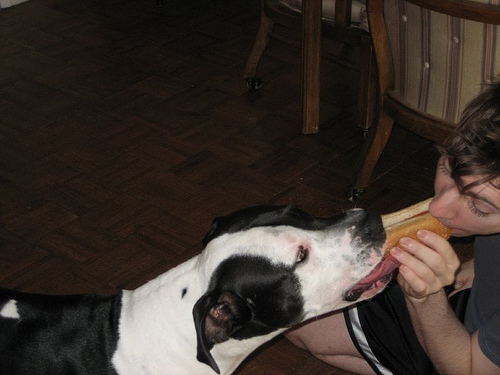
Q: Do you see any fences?
A: No, there are no fences.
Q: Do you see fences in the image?
A: No, there are no fences.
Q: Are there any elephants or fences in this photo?
A: No, there are no fences or elephants.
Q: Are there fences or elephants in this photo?
A: No, there are no fences or elephants.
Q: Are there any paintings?
A: No, there are no paintings.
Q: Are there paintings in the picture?
A: No, there are no paintings.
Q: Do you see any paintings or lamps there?
A: No, there are no paintings or lamps.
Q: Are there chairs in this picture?
A: Yes, there is a chair.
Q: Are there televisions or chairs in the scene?
A: Yes, there is a chair.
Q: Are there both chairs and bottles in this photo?
A: No, there is a chair but no bottles.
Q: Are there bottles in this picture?
A: No, there are no bottles.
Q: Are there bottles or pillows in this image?
A: No, there are no bottles or pillows.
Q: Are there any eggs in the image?
A: No, there are no eggs.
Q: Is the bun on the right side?
A: Yes, the bun is on the right of the image.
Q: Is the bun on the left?
A: No, the bun is on the right of the image.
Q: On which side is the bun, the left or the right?
A: The bun is on the right of the image.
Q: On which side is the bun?
A: The bun is on the right of the image.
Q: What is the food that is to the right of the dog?
A: The food is a bun.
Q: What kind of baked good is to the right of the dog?
A: The food is a bun.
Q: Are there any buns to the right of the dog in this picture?
A: Yes, there is a bun to the right of the dog.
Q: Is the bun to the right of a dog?
A: Yes, the bun is to the right of a dog.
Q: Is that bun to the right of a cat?
A: No, the bun is to the right of a dog.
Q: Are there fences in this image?
A: No, there are no fences.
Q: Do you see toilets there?
A: No, there are no toilets.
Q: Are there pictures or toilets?
A: No, there are no toilets or pictures.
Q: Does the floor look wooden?
A: Yes, the floor is wooden.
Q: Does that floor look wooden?
A: Yes, the floor is wooden.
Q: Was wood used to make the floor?
A: Yes, the floor is made of wood.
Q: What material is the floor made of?
A: The floor is made of wood.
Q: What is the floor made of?
A: The floor is made of wood.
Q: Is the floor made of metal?
A: No, the floor is made of wood.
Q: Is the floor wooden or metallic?
A: The floor is wooden.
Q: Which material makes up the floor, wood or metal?
A: The floor is made of wood.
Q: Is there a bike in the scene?
A: No, there are no bikes.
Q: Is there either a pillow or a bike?
A: No, there are no bikes or pillows.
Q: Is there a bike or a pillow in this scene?
A: No, there are no bikes or pillows.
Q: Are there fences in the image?
A: No, there are no fences.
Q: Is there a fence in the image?
A: No, there are no fences.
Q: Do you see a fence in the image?
A: No, there are no fences.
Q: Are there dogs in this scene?
A: Yes, there is a dog.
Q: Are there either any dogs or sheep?
A: Yes, there is a dog.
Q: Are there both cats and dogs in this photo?
A: No, there is a dog but no cats.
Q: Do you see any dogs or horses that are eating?
A: Yes, the dog is eating.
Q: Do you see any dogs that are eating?
A: Yes, there is a dog that is eating.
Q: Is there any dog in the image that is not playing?
A: Yes, there is a dog that is eating.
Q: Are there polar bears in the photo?
A: No, there are no polar bears.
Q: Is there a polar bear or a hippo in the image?
A: No, there are no polar bears or hippoes.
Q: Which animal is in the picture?
A: The animal is a dog.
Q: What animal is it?
A: The animal is a dog.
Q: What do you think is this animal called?
A: That is a dog.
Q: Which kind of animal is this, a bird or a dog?
A: That is a dog.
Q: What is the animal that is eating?
A: The animal is a dog.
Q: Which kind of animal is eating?
A: The animal is a dog.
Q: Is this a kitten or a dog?
A: This is a dog.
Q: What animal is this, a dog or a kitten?
A: This is a dog.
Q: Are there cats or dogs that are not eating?
A: No, there is a dog but it is eating.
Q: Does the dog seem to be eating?
A: Yes, the dog is eating.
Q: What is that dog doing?
A: The dog is eating.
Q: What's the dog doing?
A: The dog is eating.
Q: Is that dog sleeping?
A: No, the dog is eating.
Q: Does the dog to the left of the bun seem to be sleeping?
A: No, the dog is eating.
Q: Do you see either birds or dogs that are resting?
A: No, there is a dog but it is eating.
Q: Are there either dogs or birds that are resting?
A: No, there is a dog but it is eating.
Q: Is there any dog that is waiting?
A: No, there is a dog but it is eating.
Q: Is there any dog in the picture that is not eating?
A: No, there is a dog but it is eating.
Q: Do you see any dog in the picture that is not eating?
A: No, there is a dog but it is eating.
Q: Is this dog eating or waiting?
A: The dog is eating.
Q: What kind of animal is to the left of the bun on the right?
A: The animal is a dog.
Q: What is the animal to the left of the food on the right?
A: The animal is a dog.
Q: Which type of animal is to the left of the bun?
A: The animal is a dog.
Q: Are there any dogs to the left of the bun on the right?
A: Yes, there is a dog to the left of the bun.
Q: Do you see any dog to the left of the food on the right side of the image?
A: Yes, there is a dog to the left of the bun.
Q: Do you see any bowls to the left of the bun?
A: No, there is a dog to the left of the bun.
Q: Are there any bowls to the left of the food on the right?
A: No, there is a dog to the left of the bun.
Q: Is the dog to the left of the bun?
A: Yes, the dog is to the left of the bun.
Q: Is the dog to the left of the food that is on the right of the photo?
A: Yes, the dog is to the left of the bun.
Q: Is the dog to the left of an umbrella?
A: No, the dog is to the left of the bun.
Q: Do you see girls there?
A: No, there are no girls.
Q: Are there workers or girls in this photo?
A: No, there are no girls or workers.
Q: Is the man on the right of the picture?
A: Yes, the man is on the right of the image.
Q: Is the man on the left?
A: No, the man is on the right of the image.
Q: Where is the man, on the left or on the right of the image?
A: The man is on the right of the image.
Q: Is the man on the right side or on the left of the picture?
A: The man is on the right of the image.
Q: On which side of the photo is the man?
A: The man is on the right of the image.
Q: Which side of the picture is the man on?
A: The man is on the right of the image.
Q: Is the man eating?
A: Yes, the man is eating.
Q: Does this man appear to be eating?
A: Yes, the man is eating.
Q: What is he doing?
A: The man is eating.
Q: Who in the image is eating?
A: The man is eating.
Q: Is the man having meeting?
A: No, the man is eating.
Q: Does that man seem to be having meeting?
A: No, the man is eating.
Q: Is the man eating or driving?
A: The man is eating.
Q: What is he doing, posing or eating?
A: The man is eating.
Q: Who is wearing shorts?
A: The man is wearing shorts.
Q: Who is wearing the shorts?
A: The man is wearing shorts.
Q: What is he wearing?
A: The man is wearing shorts.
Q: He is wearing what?
A: The man is wearing shorts.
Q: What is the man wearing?
A: The man is wearing shorts.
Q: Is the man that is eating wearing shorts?
A: Yes, the man is wearing shorts.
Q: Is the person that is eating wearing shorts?
A: Yes, the man is wearing shorts.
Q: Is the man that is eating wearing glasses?
A: No, the man is wearing shorts.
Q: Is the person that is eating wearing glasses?
A: No, the man is wearing shorts.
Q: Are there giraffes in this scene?
A: No, there are no giraffes.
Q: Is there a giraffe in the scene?
A: No, there are no giraffes.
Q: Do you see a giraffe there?
A: No, there are no giraffes.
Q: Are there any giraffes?
A: No, there are no giraffes.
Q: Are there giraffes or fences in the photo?
A: No, there are no giraffes or fences.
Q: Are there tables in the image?
A: Yes, there is a table.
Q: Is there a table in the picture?
A: Yes, there is a table.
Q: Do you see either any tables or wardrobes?
A: Yes, there is a table.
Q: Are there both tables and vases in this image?
A: No, there is a table but no vases.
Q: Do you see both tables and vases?
A: No, there is a table but no vases.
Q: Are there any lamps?
A: No, there are no lamps.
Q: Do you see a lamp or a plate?
A: No, there are no lamps or plates.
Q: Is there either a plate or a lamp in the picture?
A: No, there are no lamps or plates.